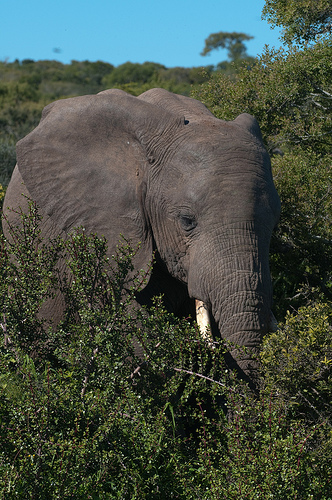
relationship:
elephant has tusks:
[0, 87, 282, 444] [194, 299, 279, 350]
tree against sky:
[198, 27, 255, 57] [1, 0, 297, 56]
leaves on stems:
[79, 249, 92, 261] [61, 242, 75, 261]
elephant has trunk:
[0, 87, 282, 444] [208, 299, 265, 461]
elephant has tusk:
[0, 87, 282, 444] [191, 297, 221, 356]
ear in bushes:
[16, 93, 153, 293] [75, 300, 270, 427]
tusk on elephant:
[181, 289, 249, 346] [22, 101, 305, 413]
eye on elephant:
[141, 188, 229, 251] [44, 105, 327, 362]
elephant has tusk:
[0, 87, 282, 444] [181, 289, 225, 351]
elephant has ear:
[0, 87, 282, 444] [13, 94, 174, 275]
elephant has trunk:
[0, 87, 282, 444] [214, 270, 268, 388]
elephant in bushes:
[0, 87, 282, 444] [10, 49, 325, 496]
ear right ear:
[16, 93, 153, 293] [24, 110, 141, 296]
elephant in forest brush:
[0, 87, 282, 444] [27, 371, 304, 453]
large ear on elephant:
[38, 101, 135, 323] [9, 85, 242, 247]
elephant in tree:
[11, 82, 268, 374] [268, 112, 329, 250]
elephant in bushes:
[0, 87, 282, 444] [7, 215, 329, 496]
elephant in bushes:
[11, 82, 268, 374] [21, 249, 327, 498]